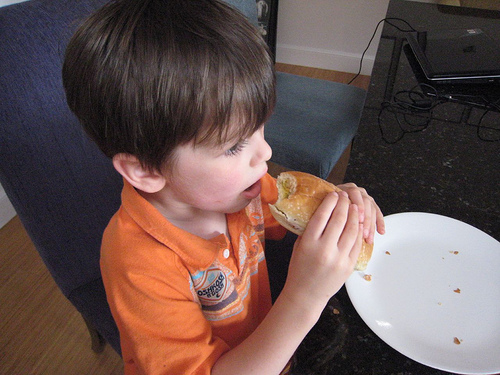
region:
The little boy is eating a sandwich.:
[123, 55, 384, 272]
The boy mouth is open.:
[238, 160, 272, 216]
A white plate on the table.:
[352, 185, 472, 360]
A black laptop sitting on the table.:
[390, 14, 492, 96]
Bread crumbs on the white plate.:
[373, 249, 468, 336]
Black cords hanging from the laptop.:
[370, 78, 495, 129]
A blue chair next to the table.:
[263, 30, 365, 160]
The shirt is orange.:
[111, 226, 265, 347]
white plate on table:
[343, 208, 498, 373]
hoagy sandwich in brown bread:
[273, 165, 380, 280]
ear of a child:
[107, 152, 166, 200]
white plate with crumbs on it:
[343, 188, 498, 373]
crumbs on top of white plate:
[355, 237, 475, 354]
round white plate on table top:
[342, 205, 498, 363]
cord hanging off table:
[349, 15, 380, 91]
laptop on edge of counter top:
[405, 26, 498, 93]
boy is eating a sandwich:
[258, 169, 390, 266]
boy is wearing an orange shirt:
[121, 202, 241, 352]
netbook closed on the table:
[401, 10, 495, 102]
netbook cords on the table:
[379, 69, 499, 128]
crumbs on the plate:
[380, 230, 477, 336]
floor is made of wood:
[3, 275, 66, 363]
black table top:
[365, 124, 485, 190]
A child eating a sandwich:
[56, 0, 416, 370]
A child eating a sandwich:
[56, 0, 386, 370]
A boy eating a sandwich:
[29, 5, 429, 373]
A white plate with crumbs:
[343, 194, 498, 374]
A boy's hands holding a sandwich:
[270, 163, 389, 299]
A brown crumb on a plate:
[440, 320, 471, 353]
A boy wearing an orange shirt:
[30, 0, 415, 374]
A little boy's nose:
[245, 130, 283, 173]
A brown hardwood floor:
[7, 293, 69, 363]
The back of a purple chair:
[4, 8, 94, 269]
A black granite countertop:
[385, 125, 490, 201]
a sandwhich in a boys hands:
[265, 166, 387, 267]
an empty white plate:
[324, 183, 498, 374]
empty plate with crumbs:
[339, 205, 499, 358]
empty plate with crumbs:
[340, 193, 498, 363]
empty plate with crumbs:
[336, 182, 498, 364]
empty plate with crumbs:
[330, 190, 492, 367]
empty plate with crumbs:
[319, 195, 488, 369]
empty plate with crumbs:
[330, 198, 492, 368]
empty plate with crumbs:
[336, 198, 495, 372]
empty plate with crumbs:
[334, 203, 496, 370]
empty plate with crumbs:
[314, 188, 498, 369]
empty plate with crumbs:
[325, 193, 492, 368]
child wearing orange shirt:
[79, 161, 239, 337]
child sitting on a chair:
[62, 133, 216, 349]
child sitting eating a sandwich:
[198, 82, 373, 314]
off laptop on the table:
[406, 26, 490, 81]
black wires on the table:
[403, 85, 456, 117]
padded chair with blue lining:
[14, 24, 75, 179]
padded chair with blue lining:
[278, 69, 330, 134]